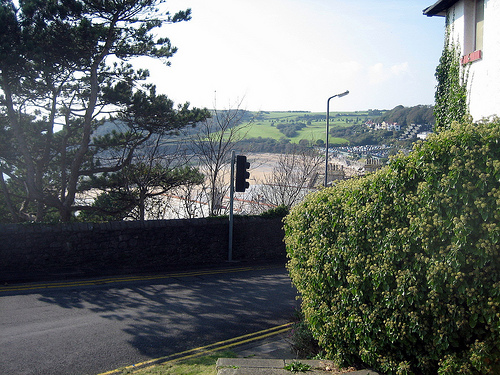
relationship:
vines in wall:
[433, 1, 472, 124] [447, 2, 497, 123]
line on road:
[88, 317, 297, 373] [4, 267, 484, 373]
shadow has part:
[43, 269, 300, 356] [213, 304, 229, 321]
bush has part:
[281, 119, 498, 372] [367, 245, 393, 270]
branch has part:
[77, 200, 134, 216] [128, 209, 141, 225]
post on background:
[325, 87, 346, 187] [77, 95, 463, 170]